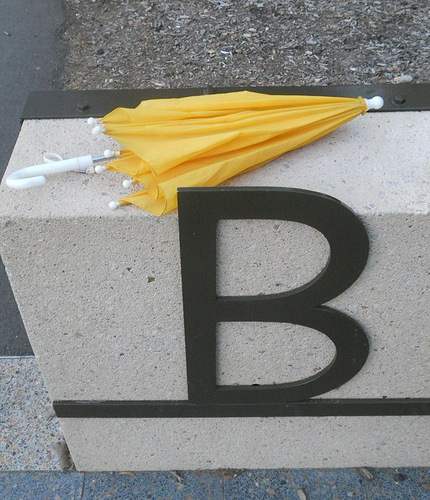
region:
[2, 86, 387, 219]
a yellow umbrella on concrete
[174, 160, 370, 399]
the word B on concrete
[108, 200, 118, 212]
the white tip of an umbrella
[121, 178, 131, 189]
the white tip of an umbrella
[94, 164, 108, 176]
the white tip of an umbrella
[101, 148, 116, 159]
the white tip of an umbrella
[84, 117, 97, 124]
the white tip of an umbrella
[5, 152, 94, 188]
the white handle of an umbrella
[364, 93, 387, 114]
the white tip of an umbrella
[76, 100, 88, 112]
a metal bolt in concrete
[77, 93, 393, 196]
yellow umbrella is closed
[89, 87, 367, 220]
yellow umbrella is closed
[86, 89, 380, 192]
yellow umbrella is closed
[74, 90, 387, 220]
yellow umbrella is closed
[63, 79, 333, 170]
yellow umbrella is closed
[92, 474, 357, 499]
dirt on the floor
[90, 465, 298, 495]
dirt on the floor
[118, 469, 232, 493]
dirt on the floor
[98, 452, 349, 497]
dirt on the floor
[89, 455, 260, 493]
dirt on the floor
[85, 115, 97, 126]
white ball on umbrella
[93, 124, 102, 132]
white ball on umbrella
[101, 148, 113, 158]
white ball on umbrella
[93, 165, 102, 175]
white ball on umbrella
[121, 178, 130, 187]
white ball on umbrella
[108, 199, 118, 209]
white ball on umbrella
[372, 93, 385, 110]
white ball on umbrella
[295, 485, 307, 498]
dried leaf on ground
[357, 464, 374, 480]
dried leaf on ground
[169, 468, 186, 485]
dried leaf on ground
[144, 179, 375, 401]
Letter on the side of the block.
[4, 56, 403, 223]
Umbrella on the block.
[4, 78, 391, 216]
Yellow color on the umbrella.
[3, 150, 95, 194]
White handle on the umbrella.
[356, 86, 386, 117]
white cap on top of the umbrella.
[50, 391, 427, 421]
Black line on the block.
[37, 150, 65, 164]
White strap on the umbrella.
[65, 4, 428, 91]
Brown mulch on the ground.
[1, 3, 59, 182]
Pavement beside the mulch.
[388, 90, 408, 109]
Black bolt on the bar.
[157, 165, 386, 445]
a black letter B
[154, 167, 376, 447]
a black letter B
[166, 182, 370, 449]
a black letter B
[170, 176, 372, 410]
a black letter B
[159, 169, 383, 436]
a black letter B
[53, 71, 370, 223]
the umbrella is yellow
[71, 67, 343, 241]
the umbrella is yellow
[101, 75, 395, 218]
the umbrella is yellow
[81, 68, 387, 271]
the umbrella is yellow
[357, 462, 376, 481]
A chip of wood.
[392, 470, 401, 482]
A chip of wood.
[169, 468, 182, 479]
A chip of wood.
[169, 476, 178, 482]
A chip of wood.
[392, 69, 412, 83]
A chip of wood.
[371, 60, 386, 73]
A chip of wood.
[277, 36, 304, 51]
A chip of wood.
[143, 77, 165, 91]
A chip of wood.